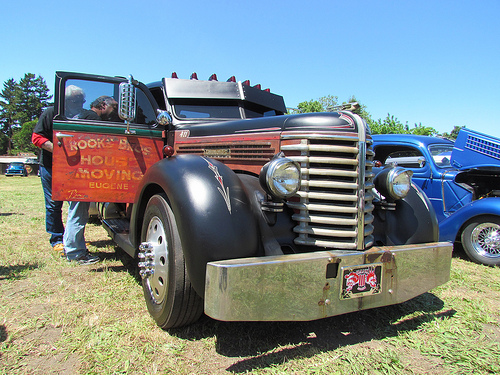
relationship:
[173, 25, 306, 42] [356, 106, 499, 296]
background has truck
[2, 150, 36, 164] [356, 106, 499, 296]
building behind truck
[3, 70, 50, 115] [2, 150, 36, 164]
tree behind building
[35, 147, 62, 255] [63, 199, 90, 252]
man wearing jeans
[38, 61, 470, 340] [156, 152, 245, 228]
vehicle has wheel hub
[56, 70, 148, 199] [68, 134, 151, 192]
door has name of business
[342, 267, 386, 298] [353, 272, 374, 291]
license plate with design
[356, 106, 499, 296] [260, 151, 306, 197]
truck has headlight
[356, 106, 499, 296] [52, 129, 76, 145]
truck has door handle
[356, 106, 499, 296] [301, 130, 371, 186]
truck has front grill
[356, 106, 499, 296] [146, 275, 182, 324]
truck has tire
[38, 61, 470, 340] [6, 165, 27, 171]
vehicle has bumper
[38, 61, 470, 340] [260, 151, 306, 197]
vehicle has headlight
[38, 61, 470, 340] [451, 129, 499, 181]
vehicle has hood up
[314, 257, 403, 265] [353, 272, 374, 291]
fender has design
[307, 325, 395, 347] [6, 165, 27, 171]
shadow underneath bumper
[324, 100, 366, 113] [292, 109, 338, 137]
ornament on hood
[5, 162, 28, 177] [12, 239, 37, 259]
car on grass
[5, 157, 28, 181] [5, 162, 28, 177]
car behind car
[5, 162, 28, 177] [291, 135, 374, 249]
car has light on front grill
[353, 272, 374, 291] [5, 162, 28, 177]
design on front of car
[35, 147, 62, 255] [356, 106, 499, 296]
man looking into truck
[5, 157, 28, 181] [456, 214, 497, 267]
car has wheel